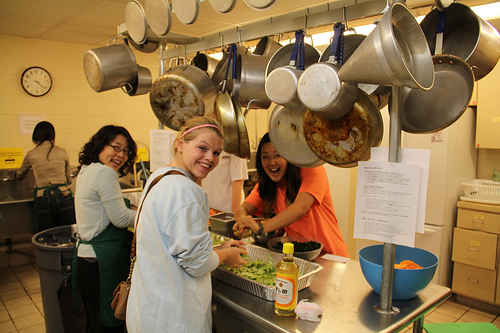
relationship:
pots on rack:
[82, 2, 496, 167] [154, 0, 499, 62]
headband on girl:
[175, 121, 232, 138] [113, 109, 261, 329]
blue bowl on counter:
[360, 242, 435, 287] [316, 247, 371, 332]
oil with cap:
[274, 257, 298, 314] [284, 240, 294, 254]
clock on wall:
[22, 65, 52, 95] [2, 36, 156, 165]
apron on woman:
[60, 181, 134, 324] [82, 100, 250, 332]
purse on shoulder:
[114, 219, 128, 324] [160, 163, 201, 206]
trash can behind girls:
[7, 200, 123, 321] [67, 87, 359, 278]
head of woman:
[170, 114, 225, 181] [113, 115, 240, 329]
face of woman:
[188, 130, 224, 179] [125, 115, 248, 331]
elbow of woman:
[181, 254, 207, 288] [125, 115, 248, 331]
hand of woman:
[215, 240, 251, 274] [125, 118, 214, 331]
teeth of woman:
[196, 161, 210, 168] [125, 115, 248, 331]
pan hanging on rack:
[386, 52, 480, 136] [116, 2, 498, 54]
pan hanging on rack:
[386, 52, 480, 136] [118, 3, 487, 59]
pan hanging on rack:
[228, 50, 264, 97] [185, 1, 397, 49]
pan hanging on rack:
[386, 52, 480, 136] [190, 22, 293, 44]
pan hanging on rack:
[152, 52, 220, 134] [156, 0, 474, 73]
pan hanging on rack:
[398, 55, 473, 132] [154, 0, 499, 62]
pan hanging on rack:
[386, 52, 480, 136] [115, 8, 481, 105]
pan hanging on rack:
[386, 52, 480, 136] [147, 10, 493, 74]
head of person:
[170, 114, 225, 181] [125, 116, 245, 332]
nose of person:
[199, 149, 214, 163] [110, 113, 246, 331]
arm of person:
[257, 165, 327, 235] [232, 131, 347, 258]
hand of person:
[223, 246, 250, 269] [125, 116, 245, 332]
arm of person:
[257, 165, 327, 235] [125, 116, 245, 332]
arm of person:
[97, 171, 135, 228] [74, 125, 136, 331]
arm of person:
[229, 156, 246, 223] [197, 151, 247, 223]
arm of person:
[14, 155, 30, 179] [15, 120, 75, 227]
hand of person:
[223, 246, 250, 269] [240, 126, 356, 262]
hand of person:
[223, 246, 250, 269] [131, 111, 228, 330]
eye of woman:
[196, 142, 207, 152] [125, 115, 248, 331]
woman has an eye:
[125, 115, 248, 331] [196, 142, 207, 152]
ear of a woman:
[174, 135, 184, 154] [124, 115, 223, 331]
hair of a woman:
[159, 108, 229, 146] [110, 75, 250, 317]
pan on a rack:
[386, 52, 480, 136] [88, 6, 498, 148]